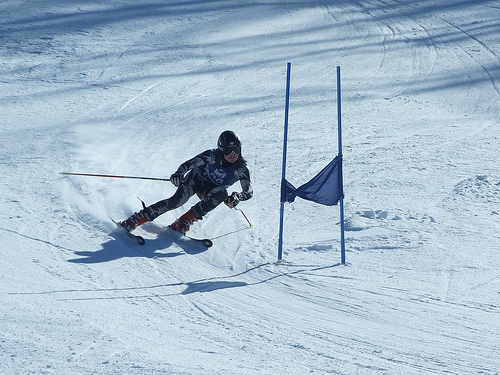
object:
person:
[122, 130, 254, 233]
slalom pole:
[276, 62, 292, 261]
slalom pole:
[336, 65, 346, 264]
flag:
[284, 155, 341, 206]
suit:
[148, 148, 255, 221]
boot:
[122, 210, 149, 232]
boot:
[170, 208, 198, 234]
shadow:
[67, 226, 208, 263]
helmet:
[218, 130, 241, 148]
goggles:
[218, 145, 241, 156]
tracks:
[349, 3, 500, 101]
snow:
[1, 2, 499, 374]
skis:
[108, 215, 146, 247]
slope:
[0, 2, 498, 374]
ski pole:
[60, 172, 173, 181]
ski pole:
[227, 196, 253, 227]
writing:
[210, 168, 227, 184]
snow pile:
[342, 210, 436, 233]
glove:
[169, 172, 184, 187]